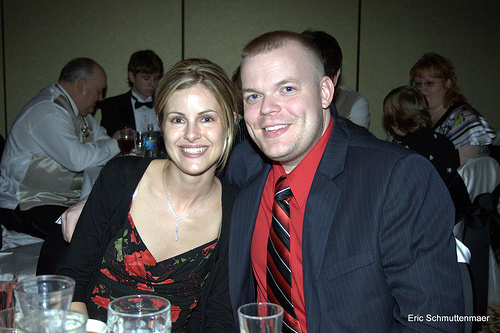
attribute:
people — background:
[0, 31, 496, 332]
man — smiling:
[54, 29, 466, 331]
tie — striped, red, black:
[266, 174, 302, 333]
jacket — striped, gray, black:
[224, 113, 466, 332]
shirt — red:
[249, 117, 334, 333]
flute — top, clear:
[236, 301, 287, 332]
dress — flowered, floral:
[88, 209, 219, 329]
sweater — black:
[47, 155, 246, 333]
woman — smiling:
[57, 58, 246, 332]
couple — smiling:
[50, 31, 466, 333]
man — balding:
[1, 56, 132, 291]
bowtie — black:
[128, 92, 155, 110]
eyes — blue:
[249, 85, 292, 100]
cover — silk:
[456, 155, 500, 202]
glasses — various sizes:
[0, 275, 285, 333]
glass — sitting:
[115, 126, 136, 154]